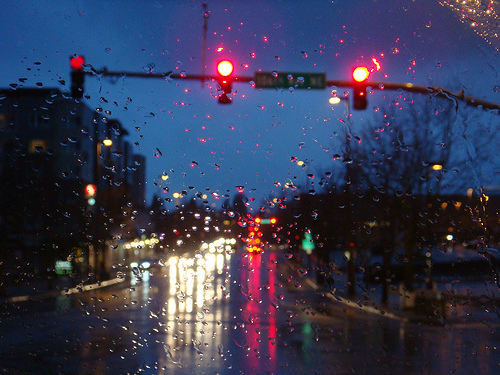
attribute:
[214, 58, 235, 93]
light — traffic, lit, red, stop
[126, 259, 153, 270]
headlights — pair, on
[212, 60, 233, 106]
light — red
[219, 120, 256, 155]
clouds — white 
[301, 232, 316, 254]
sign — reflecting, green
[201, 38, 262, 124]
signal light — red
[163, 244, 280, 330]
lights — street, reflecting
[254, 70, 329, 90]
sign — green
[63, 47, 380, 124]
traffic light — long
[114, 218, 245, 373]
light — reflecting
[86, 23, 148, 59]
clouds — white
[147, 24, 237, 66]
clouds — white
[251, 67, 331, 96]
street sign — green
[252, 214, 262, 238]
stop light — red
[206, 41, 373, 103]
light — red, stop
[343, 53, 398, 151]
light — red, traffic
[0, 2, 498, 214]
sky — blue, dark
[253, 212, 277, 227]
lights — street, red